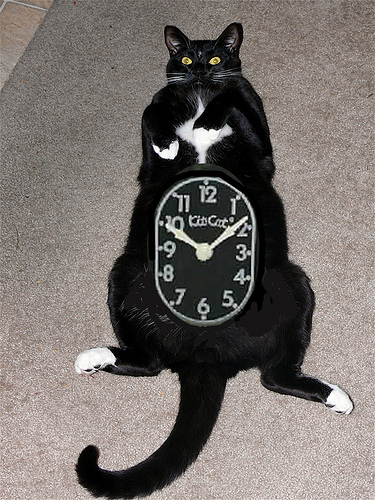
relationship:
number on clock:
[197, 181, 220, 205] [156, 177, 257, 324]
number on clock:
[224, 198, 239, 224] [156, 177, 257, 324]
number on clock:
[236, 242, 250, 264] [156, 177, 257, 324]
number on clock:
[234, 268, 247, 288] [156, 177, 257, 324]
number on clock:
[219, 289, 238, 313] [156, 177, 257, 324]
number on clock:
[194, 298, 213, 321] [156, 177, 257, 324]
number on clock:
[165, 288, 191, 311] [156, 177, 257, 324]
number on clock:
[160, 264, 175, 285] [156, 177, 257, 324]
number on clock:
[159, 239, 178, 262] [156, 177, 257, 324]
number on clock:
[165, 214, 184, 234] [156, 177, 257, 324]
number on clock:
[238, 221, 252, 240] [156, 177, 257, 324]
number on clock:
[173, 190, 193, 217] [156, 177, 257, 324]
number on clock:
[171, 287, 187, 309] [156, 177, 257, 324]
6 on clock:
[197, 297, 211, 320] [156, 177, 257, 324]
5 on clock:
[219, 289, 238, 309] [156, 177, 257, 324]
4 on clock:
[231, 267, 250, 287] [156, 177, 257, 324]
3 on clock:
[235, 244, 249, 261] [156, 177, 257, 324]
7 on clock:
[172, 287, 188, 308] [156, 177, 257, 324]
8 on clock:
[160, 263, 174, 284] [156, 177, 257, 324]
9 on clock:
[161, 236, 177, 259] [156, 177, 257, 324]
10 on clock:
[167, 214, 184, 236] [156, 177, 257, 324]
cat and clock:
[77, 20, 353, 499] [156, 177, 257, 324]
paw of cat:
[193, 116, 223, 143] [77, 20, 353, 499]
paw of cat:
[151, 131, 182, 162] [77, 20, 353, 499]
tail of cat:
[75, 381, 227, 499] [77, 20, 353, 499]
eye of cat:
[206, 53, 224, 67] [77, 20, 353, 499]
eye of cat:
[179, 56, 193, 68] [77, 20, 353, 499]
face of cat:
[167, 42, 240, 89] [77, 20, 353, 499]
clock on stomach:
[156, 177, 257, 324] [152, 158, 268, 342]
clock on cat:
[156, 177, 257, 324] [77, 20, 353, 499]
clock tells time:
[156, 177, 257, 324] [160, 214, 251, 262]